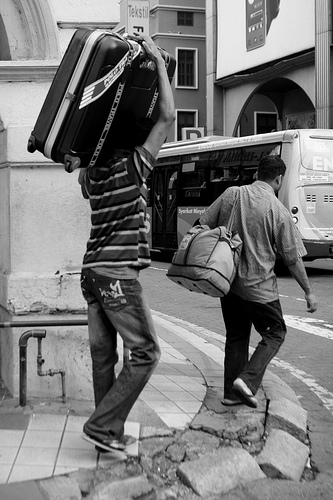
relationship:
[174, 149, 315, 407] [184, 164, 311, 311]
man wearing shirt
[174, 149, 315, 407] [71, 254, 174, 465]
man wearing pants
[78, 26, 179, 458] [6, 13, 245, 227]
man carrying suitcase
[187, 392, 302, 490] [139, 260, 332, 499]
curb beside street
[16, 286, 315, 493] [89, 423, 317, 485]
sidewalk has curb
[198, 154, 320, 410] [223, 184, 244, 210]
man has shoulder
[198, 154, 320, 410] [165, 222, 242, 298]
man has bag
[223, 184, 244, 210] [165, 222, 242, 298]
shoulder has bag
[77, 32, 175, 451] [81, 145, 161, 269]
man wearing shirt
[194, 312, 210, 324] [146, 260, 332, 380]
brick on road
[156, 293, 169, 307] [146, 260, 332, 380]
brick on road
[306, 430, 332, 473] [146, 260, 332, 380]
brick on road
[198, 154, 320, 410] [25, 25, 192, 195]
man carrying suitcase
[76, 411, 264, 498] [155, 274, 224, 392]
rocks on ground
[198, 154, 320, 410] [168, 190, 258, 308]
man carrying luggage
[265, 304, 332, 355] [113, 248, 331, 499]
line on road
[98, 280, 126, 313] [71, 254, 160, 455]
design on pants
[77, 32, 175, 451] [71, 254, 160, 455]
man wearing pants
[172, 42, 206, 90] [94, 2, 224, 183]
window on building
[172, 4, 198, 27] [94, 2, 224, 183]
window on building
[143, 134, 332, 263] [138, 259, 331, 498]
bus on road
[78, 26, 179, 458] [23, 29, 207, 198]
man holding bag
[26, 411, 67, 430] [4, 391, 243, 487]
square on sidewalk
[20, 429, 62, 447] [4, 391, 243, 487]
square on sidewalk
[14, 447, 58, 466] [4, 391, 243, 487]
square on sidewalk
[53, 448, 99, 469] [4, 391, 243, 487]
square on sidewalk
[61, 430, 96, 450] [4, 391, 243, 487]
square on sidewalk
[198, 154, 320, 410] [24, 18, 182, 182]
man carrying suitcase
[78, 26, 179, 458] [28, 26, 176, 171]
man carrying luggage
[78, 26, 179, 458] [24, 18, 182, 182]
man holding suitcase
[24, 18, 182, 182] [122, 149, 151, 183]
suitcase on shoulder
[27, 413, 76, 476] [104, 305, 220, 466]
square tiles covering sidewalk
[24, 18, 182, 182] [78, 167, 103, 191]
suitcase on shoulder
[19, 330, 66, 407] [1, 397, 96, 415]
pipes jutting from concrete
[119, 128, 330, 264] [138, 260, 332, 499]
bus on street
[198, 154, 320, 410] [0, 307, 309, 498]
man walking on sidewalk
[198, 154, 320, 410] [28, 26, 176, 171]
man carrying luggage